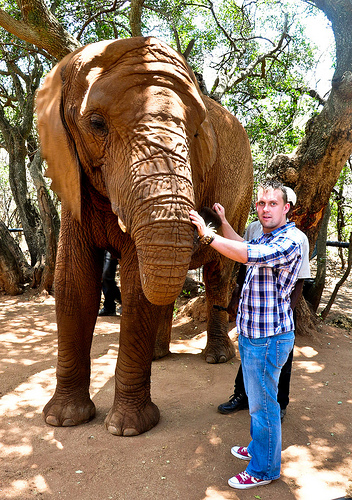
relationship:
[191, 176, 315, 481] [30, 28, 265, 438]
man next to elephant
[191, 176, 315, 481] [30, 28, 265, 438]
man touching elephant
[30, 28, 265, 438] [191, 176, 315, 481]
elephant next to man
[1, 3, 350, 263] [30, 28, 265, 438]
trees behind elephant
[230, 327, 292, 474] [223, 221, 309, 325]
jeans below shirt